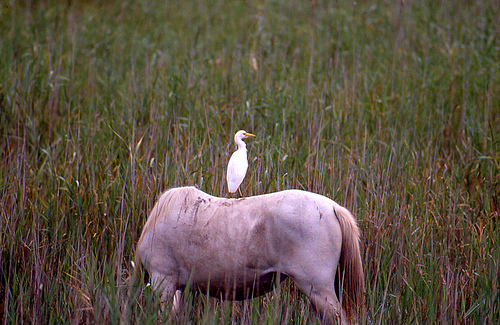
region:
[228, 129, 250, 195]
this is a bird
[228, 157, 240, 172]
the bird is white in color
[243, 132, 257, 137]
this is the beak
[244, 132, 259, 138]
the beak is yellow in color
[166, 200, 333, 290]
this is a horse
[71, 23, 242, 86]
this is a grass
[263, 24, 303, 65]
the grass is green in color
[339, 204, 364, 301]
this is the tail of the horse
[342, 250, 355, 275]
the fur is brown in color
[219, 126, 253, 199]
the bird is on the back of the hiorse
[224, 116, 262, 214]
This bird is a very bright what in color with an orange beak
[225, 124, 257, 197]
This tall bird is sitting on the back of a horse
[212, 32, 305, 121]
The color of this grass is a light brown in color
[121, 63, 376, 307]
This photo was taken last week by Jake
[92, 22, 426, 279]
This photo was taken in the year of 2015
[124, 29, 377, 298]
This photo was taken in the state of Kentucky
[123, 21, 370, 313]
This photo was taken outside the city of Louisville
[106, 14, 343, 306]
This photo won an award for best capture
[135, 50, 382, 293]
This photo is very clear in appearance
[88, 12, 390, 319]
This photo was captured using a great telephoto lens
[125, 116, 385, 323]
a horse and a bird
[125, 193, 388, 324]
a horse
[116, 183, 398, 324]
a horse in a field of high grass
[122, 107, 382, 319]
a horse and a bird in a field of tall grass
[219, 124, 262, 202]
the bird is white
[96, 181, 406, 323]
the horse has it's head down in the grass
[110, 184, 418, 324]
the horse is white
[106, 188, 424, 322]
the horse is grazing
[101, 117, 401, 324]
the bird is standing on the horse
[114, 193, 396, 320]
the horse is dirty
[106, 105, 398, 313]
A couple symbiotic friends.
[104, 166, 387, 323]
A horse eating grass.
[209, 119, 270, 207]
A bird riding bareback on the horse.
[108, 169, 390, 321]
A white horse.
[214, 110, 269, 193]
A white bird.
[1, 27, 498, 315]
A very grassy field.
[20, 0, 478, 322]
Much of the grass is dry and brown.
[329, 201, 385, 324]
A long horse tail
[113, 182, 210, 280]
The horse's mane.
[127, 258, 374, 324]
Four horse legs.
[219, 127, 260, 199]
a white bird on the horse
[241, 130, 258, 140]
the yellow beak of a bird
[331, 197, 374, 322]
the tail of a horse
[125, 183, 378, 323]
a gray horse in the grass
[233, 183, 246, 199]
the leg of a bird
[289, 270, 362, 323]
the leg of a horse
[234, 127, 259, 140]
the head of a bird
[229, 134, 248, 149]
the neck of a bird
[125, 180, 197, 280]
the mane of a horse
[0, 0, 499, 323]
a green grassy field